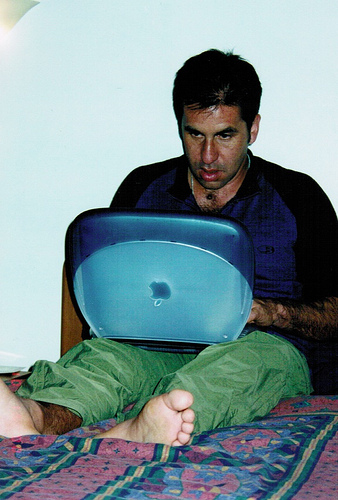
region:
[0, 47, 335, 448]
a man on a laptop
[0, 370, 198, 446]
the man has feet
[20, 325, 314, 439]
the pants are green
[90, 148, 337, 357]
the shirt is black and blue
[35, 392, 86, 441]
the man's leg is hairy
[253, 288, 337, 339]
the man's arm is hairy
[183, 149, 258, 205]
the man is wearing a necklace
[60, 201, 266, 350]
the laptop is blue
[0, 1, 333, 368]
the wall is plain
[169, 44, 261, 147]
the man has black hair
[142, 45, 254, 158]
man with black hair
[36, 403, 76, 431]
man with hair in its leg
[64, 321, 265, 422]
man with green pants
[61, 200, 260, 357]
man holding a laptop computer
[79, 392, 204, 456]
man barefoot on the bed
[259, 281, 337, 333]
man with hair on his arm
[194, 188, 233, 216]
man with hair on his chest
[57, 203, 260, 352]
man holding a blue laptop computer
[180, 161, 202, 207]
man wearing a silver chain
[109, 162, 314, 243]
man wearing a blue and black shirt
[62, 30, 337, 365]
a man on a mac book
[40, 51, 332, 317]
a man typing on a laptop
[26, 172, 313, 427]
an older version of a macbook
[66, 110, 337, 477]
a man sitting on a bed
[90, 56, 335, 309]
a man with black hair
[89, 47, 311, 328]
a man wearing a shirt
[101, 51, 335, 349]
a man wearing black and blue shirt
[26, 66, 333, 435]
a man wearing pants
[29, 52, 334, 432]
a man wearing green pants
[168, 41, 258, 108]
Man has dark hair.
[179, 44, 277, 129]
Man has short hair.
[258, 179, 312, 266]
Man wearing blue and black shirt.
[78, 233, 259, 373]
Man using laptop computer.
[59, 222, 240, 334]
Laptop is gray in color.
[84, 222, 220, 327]
Laptop is an apple brand.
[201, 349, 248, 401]
Man wearing green pants.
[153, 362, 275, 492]
Man sitting on top of bed.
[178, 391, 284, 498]
Bed spread is multi colored.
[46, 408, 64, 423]
Man has dark hair on legs.